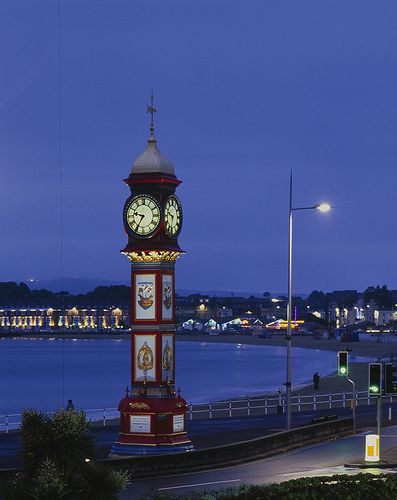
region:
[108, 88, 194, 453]
a small, red clock tower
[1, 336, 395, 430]
a calm body of water behind the clock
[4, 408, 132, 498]
a green bush in front of the clock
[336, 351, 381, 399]
two green traffic signals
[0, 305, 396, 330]
lit up buildings behind the water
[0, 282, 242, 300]
trees behind the buildings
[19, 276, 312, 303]
mountains behind the trees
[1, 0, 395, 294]
a dark evening sky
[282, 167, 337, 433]
a lit streetlight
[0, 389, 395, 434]
a white fence behind the clock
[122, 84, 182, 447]
Stunning clock tower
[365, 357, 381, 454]
Traffic light is green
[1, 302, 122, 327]
Large lit up building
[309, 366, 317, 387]
Man in black standing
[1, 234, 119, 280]
Darkened skyline at dusk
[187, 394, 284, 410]
Silver metal safety railing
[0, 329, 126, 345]
Lights reflecting off the water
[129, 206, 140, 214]
Black clock hour hand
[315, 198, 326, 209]
Brightly elluminating light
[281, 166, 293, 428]
Very tall metal light pole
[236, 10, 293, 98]
part of the sky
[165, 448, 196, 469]
part of a boundary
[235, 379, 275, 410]
part of a fence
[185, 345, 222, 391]
part of a water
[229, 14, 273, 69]
part of the sky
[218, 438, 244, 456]
edge of a fence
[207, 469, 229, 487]
part of a line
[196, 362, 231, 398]
part of a water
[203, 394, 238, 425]
part of a fence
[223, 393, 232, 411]
part of a pole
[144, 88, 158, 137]
weather vane on top of tower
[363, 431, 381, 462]
white and yellow lit up box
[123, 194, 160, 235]
greenish clock face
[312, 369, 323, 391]
person standing near the water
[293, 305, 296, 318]
purple light pole in the background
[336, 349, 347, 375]
green street light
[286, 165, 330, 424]
light on light pole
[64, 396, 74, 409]
person walking behind bush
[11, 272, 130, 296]
mountains in the background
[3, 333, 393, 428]
body of water